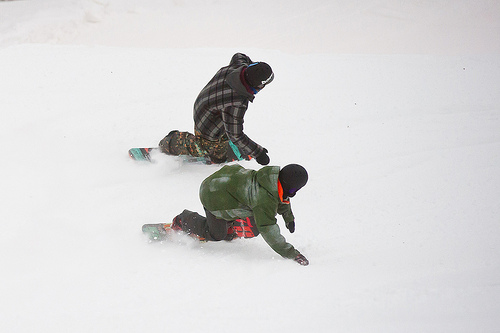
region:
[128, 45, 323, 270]
two children playing in the snow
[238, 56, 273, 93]
head of a child looking down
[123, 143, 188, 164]
ski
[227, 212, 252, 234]
pink design on snowsuit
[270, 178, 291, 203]
pink collar on the snowsuit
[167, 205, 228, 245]
leg of skiier on the ski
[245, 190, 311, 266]
front right arm touching snow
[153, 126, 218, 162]
leg of skiier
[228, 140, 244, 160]
blue design on skiier's snowsuit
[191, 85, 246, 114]
black stripe on skiier's snowsuit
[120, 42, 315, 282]
two snowboarders snowboarding in the snow.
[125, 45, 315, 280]
two snowboarders snowboarding in the snow.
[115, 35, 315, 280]
two snowboarders snowboarding in the snow.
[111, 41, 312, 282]
two snowboarders snowboarding in the snow.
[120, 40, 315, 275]
two snowboarders snowboarding in the snow.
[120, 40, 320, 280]
two snowboarders snowboarding in the snow.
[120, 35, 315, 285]
two snowboarders snowboarding in the snow.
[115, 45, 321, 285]
two snowboarders snowboarding in the snow.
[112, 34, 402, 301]
they are racing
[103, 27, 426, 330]
they are snowboarding in tandem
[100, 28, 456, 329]
they are leaning towards the ground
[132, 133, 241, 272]
snow spray from the speed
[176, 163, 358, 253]
his jacket is green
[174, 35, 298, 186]
his jacket has stripes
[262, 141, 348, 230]
he is wearing a black cap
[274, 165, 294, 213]
the lining of his jacket is orange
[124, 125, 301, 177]
his snowboard is blue, orange, and black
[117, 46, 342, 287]
There are two snowboarders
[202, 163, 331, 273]
The jacket is green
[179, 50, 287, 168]
The jacket is black and grey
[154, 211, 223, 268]
The snow is kicking up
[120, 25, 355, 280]
The snowboarders are on the snow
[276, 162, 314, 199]
The hat is black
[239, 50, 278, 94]
The helmet is black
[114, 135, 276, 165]
The snowboard is multicolored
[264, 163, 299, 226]
There is orange around the snowboarders neck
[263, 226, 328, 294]
The hand touches the ground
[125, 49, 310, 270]
Two men snowboarding in the snow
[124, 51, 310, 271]
Two men riding snowboards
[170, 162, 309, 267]
Man wearing an olive green coat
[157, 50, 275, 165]
Man wearing a gray plaid coat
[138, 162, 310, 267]
Man leaning on a snowboard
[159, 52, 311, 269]
Two men in snow caps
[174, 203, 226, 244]
gray snow pants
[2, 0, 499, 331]
Snow covered ground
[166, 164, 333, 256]
A person is playing.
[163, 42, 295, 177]
A person is playing.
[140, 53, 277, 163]
A person on some snow.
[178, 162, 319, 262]
A person on some snow.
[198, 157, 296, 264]
A piece of clothing.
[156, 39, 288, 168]
A person is standing up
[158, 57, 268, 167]
A person is playing.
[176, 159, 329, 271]
A person is playing.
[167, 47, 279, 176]
A person on some snow.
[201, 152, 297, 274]
A piece of clothing.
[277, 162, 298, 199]
A piece of clothing.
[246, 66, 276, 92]
A piece of clothing.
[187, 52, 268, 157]
A piece of clothing.